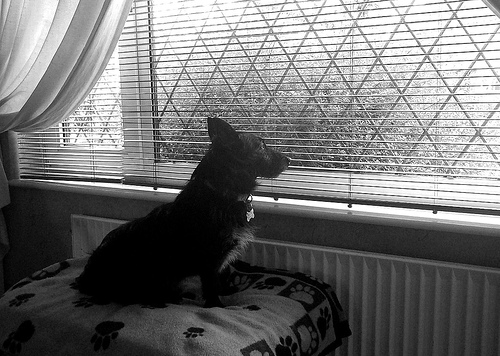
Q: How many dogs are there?
A: 1.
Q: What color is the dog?
A: Black.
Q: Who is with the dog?
A: No one.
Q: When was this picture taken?
A: During the day.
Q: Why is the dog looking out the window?
A: Looking for his owner.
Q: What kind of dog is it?
A: Terrier.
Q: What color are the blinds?
A: White.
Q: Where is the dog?
A: On a stool.